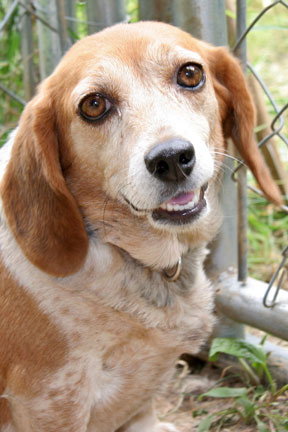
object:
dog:
[0, 20, 283, 431]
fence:
[209, 2, 288, 388]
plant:
[191, 329, 288, 431]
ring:
[163, 255, 182, 282]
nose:
[143, 135, 196, 184]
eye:
[77, 91, 115, 121]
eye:
[175, 60, 206, 91]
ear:
[208, 44, 284, 209]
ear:
[0, 94, 88, 276]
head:
[1, 21, 284, 282]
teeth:
[160, 202, 194, 212]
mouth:
[160, 189, 206, 220]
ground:
[169, 358, 285, 431]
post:
[86, 2, 128, 37]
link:
[230, 1, 288, 52]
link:
[230, 168, 288, 213]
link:
[262, 247, 287, 308]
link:
[0, 0, 61, 39]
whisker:
[194, 147, 249, 193]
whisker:
[102, 151, 146, 236]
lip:
[156, 206, 202, 221]